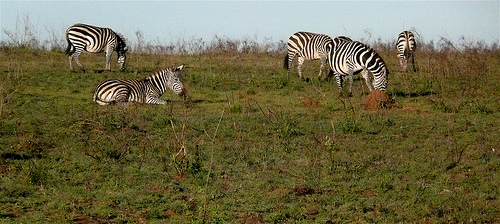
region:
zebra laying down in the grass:
[107, 57, 195, 116]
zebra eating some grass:
[53, 14, 140, 70]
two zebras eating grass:
[240, 26, 391, 136]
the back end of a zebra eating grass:
[394, 19, 444, 93]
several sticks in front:
[125, 117, 245, 215]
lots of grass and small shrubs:
[71, 116, 430, 205]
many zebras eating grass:
[16, 7, 430, 144]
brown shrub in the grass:
[344, 86, 401, 121]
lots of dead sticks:
[141, 26, 276, 62]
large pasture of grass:
[61, 109, 436, 201]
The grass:
[198, 124, 272, 194]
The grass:
[261, 157, 331, 217]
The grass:
[200, 98, 360, 219]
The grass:
[238, 113, 343, 193]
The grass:
[230, 143, 298, 173]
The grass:
[218, 143, 314, 211]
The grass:
[236, 123, 446, 214]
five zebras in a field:
[40, 12, 449, 134]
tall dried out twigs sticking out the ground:
[165, 91, 210, 187]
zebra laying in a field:
[85, 59, 196, 119]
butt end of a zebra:
[390, 20, 423, 80]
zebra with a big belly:
[62, 20, 137, 76]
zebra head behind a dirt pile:
[360, 54, 405, 114]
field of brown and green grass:
[10, 36, 498, 216]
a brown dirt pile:
[365, 82, 400, 120]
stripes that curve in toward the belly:
[67, 20, 118, 67]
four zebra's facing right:
[7, 16, 400, 127]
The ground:
[225, 156, 319, 221]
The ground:
[276, 154, 338, 219]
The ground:
[254, 149, 333, 190]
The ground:
[259, 154, 296, 214]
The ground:
[270, 128, 356, 207]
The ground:
[253, 177, 310, 216]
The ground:
[304, 137, 347, 217]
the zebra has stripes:
[184, 14, 496, 96]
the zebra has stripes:
[230, 7, 362, 128]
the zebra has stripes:
[219, 21, 434, 221]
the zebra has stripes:
[282, 31, 387, 211]